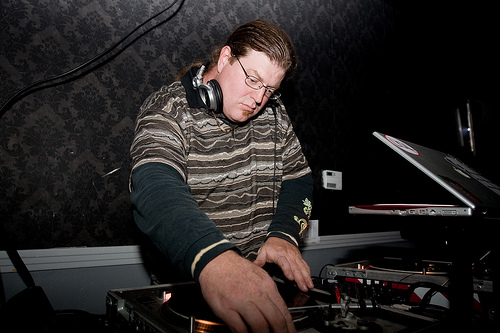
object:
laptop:
[346, 130, 500, 218]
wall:
[1, 0, 437, 273]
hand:
[194, 248, 298, 332]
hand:
[252, 235, 315, 292]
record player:
[102, 263, 425, 332]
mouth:
[238, 102, 256, 111]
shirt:
[124, 79, 318, 284]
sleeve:
[127, 161, 246, 284]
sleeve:
[262, 168, 317, 246]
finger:
[219, 310, 250, 333]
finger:
[271, 253, 298, 282]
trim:
[0, 244, 142, 274]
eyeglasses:
[229, 49, 285, 101]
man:
[127, 18, 319, 333]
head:
[212, 18, 296, 124]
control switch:
[318, 168, 346, 192]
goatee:
[240, 109, 255, 117]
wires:
[314, 261, 338, 279]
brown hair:
[172, 19, 299, 84]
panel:
[321, 168, 346, 192]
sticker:
[384, 132, 424, 156]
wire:
[0, 1, 182, 114]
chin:
[229, 109, 253, 124]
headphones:
[178, 62, 223, 117]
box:
[321, 169, 346, 191]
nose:
[251, 86, 270, 104]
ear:
[215, 44, 234, 74]